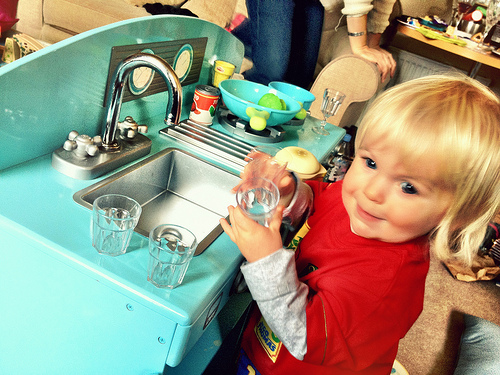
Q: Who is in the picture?
A: A boy.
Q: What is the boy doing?
A: Playing.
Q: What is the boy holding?
A: A glass.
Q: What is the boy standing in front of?
A: A stove.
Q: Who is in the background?
A: A woman.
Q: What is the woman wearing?
A: Jeans.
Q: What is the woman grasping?
A: A sofa.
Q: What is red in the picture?
A: The boy's shirt.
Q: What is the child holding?
A: A toy glass.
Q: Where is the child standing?
A: In front of a toy sink.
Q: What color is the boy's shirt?
A: Red and gray.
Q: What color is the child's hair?
A: Blonde.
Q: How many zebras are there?
A: Zero.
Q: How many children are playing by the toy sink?
A: One.